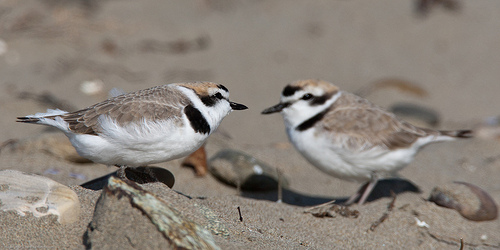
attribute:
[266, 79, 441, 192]
bird — white, brown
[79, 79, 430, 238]
rock — small, dark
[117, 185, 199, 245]
leaf — green, brown